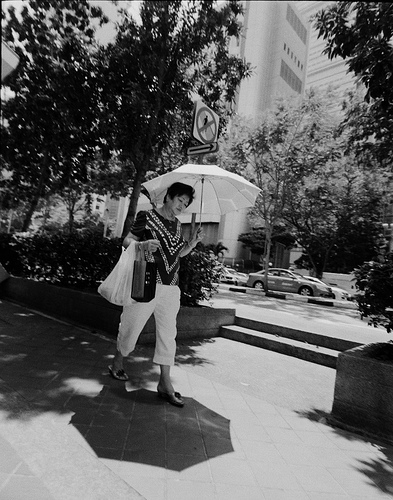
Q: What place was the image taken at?
A: It was taken at the street.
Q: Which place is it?
A: It is a street.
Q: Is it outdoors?
A: Yes, it is outdoors.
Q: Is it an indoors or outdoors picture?
A: It is outdoors.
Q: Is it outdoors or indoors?
A: It is outdoors.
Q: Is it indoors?
A: No, it is outdoors.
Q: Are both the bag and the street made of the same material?
A: No, the bag is made of plastic and the street is made of concrete.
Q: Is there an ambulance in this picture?
A: No, there are no ambulances.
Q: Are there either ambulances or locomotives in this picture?
A: No, there are no ambulances or locomotives.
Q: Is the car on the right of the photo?
A: Yes, the car is on the right of the image.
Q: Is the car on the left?
A: No, the car is on the right of the image.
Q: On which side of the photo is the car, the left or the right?
A: The car is on the right of the image.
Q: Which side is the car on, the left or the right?
A: The car is on the right of the image.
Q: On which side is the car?
A: The car is on the right of the image.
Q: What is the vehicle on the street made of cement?
A: The vehicle is a car.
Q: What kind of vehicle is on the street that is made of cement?
A: The vehicle is a car.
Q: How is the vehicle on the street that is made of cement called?
A: The vehicle is a car.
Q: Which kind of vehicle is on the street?
A: The vehicle is a car.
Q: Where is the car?
A: The car is on the street.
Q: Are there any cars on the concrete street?
A: Yes, there is a car on the street.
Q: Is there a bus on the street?
A: No, there is a car on the street.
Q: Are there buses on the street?
A: No, there is a car on the street.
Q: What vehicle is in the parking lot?
A: The vehicle is a car.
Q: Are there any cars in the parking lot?
A: Yes, there is a car in the parking lot.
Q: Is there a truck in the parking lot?
A: No, there is a car in the parking lot.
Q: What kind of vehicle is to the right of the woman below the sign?
A: The vehicle is a car.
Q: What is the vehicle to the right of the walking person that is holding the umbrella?
A: The vehicle is a car.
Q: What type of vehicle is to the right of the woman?
A: The vehicle is a car.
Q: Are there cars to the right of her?
A: Yes, there is a car to the right of the woman.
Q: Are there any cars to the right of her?
A: Yes, there is a car to the right of the woman.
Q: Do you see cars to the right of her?
A: Yes, there is a car to the right of the woman.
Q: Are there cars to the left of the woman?
A: No, the car is to the right of the woman.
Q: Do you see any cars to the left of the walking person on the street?
A: No, the car is to the right of the woman.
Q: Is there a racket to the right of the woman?
A: No, there is a car to the right of the woman.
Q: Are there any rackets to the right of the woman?
A: No, there is a car to the right of the woman.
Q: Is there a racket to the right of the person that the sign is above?
A: No, there is a car to the right of the woman.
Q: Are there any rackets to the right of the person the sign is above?
A: No, there is a car to the right of the woman.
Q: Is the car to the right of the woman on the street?
A: Yes, the car is to the right of the woman.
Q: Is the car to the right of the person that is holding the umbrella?
A: Yes, the car is to the right of the woman.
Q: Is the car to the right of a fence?
A: No, the car is to the right of the woman.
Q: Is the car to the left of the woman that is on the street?
A: No, the car is to the right of the woman.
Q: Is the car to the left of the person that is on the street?
A: No, the car is to the right of the woman.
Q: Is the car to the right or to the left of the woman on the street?
A: The car is to the right of the woman.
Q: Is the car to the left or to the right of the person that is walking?
A: The car is to the right of the woman.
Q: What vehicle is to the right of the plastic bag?
A: The vehicle is a car.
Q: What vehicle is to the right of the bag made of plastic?
A: The vehicle is a car.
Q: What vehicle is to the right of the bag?
A: The vehicle is a car.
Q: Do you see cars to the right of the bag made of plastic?
A: Yes, there is a car to the right of the bag.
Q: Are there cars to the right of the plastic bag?
A: Yes, there is a car to the right of the bag.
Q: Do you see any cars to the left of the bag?
A: No, the car is to the right of the bag.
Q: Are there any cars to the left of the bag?
A: No, the car is to the right of the bag.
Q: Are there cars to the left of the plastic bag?
A: No, the car is to the right of the bag.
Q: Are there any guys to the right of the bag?
A: No, there is a car to the right of the bag.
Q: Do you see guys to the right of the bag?
A: No, there is a car to the right of the bag.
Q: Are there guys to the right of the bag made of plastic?
A: No, there is a car to the right of the bag.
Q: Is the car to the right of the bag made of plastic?
A: Yes, the car is to the right of the bag.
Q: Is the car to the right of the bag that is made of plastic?
A: Yes, the car is to the right of the bag.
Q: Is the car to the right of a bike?
A: No, the car is to the right of the bag.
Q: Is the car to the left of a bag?
A: No, the car is to the right of a bag.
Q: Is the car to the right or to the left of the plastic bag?
A: The car is to the right of the bag.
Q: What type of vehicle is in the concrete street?
A: The vehicle is a car.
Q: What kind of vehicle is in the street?
A: The vehicle is a car.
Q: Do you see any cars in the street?
A: Yes, there is a car in the street.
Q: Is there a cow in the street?
A: No, there is a car in the street.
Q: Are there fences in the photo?
A: No, there are no fences.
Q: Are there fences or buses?
A: No, there are no fences or buses.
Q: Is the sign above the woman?
A: Yes, the sign is above the woman.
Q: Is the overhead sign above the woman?
A: Yes, the sign is above the woman.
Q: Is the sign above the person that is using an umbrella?
A: Yes, the sign is above the woman.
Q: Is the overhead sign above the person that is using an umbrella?
A: Yes, the sign is above the woman.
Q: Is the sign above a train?
A: No, the sign is above the woman.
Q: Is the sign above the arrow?
A: Yes, the sign is above the arrow.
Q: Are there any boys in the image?
A: No, there are no boys.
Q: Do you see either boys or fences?
A: No, there are no boys or fences.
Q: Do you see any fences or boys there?
A: No, there are no boys or fences.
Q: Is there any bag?
A: Yes, there is a bag.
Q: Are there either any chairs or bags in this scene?
A: Yes, there is a bag.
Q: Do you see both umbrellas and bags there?
A: Yes, there are both a bag and an umbrella.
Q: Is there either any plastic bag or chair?
A: Yes, there is a plastic bag.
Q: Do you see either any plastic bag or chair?
A: Yes, there is a plastic bag.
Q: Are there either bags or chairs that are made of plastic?
A: Yes, the bag is made of plastic.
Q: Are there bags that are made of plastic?
A: Yes, there is a bag that is made of plastic.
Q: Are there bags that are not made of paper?
A: Yes, there is a bag that is made of plastic.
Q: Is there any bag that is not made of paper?
A: Yes, there is a bag that is made of plastic.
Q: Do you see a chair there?
A: No, there are no chairs.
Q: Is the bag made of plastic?
A: Yes, the bag is made of plastic.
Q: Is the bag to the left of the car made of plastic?
A: Yes, the bag is made of plastic.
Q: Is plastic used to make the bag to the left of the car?
A: Yes, the bag is made of plastic.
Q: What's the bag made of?
A: The bag is made of plastic.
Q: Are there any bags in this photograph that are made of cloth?
A: No, there is a bag but it is made of plastic.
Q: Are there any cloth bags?
A: No, there is a bag but it is made of plastic.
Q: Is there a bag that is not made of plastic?
A: No, there is a bag but it is made of plastic.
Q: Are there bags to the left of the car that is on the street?
A: Yes, there is a bag to the left of the car.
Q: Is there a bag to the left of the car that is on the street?
A: Yes, there is a bag to the left of the car.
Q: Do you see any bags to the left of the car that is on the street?
A: Yes, there is a bag to the left of the car.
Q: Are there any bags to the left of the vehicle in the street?
A: Yes, there is a bag to the left of the car.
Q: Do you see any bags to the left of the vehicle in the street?
A: Yes, there is a bag to the left of the car.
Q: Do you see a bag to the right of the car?
A: No, the bag is to the left of the car.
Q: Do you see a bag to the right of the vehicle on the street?
A: No, the bag is to the left of the car.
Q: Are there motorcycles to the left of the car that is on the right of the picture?
A: No, there is a bag to the left of the car.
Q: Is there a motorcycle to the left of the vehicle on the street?
A: No, there is a bag to the left of the car.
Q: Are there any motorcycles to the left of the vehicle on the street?
A: No, there is a bag to the left of the car.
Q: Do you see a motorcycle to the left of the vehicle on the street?
A: No, there is a bag to the left of the car.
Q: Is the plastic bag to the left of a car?
A: Yes, the bag is to the left of a car.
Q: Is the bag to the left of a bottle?
A: No, the bag is to the left of a car.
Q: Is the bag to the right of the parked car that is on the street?
A: No, the bag is to the left of the car.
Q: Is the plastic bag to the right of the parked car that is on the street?
A: No, the bag is to the left of the car.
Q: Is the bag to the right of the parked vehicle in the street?
A: No, the bag is to the left of the car.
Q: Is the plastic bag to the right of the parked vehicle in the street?
A: No, the bag is to the left of the car.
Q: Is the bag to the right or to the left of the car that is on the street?
A: The bag is to the left of the car.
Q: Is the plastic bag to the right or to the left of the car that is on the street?
A: The bag is to the left of the car.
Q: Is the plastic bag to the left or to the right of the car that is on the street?
A: The bag is to the left of the car.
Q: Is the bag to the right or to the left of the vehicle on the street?
A: The bag is to the left of the car.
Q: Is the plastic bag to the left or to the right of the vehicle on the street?
A: The bag is to the left of the car.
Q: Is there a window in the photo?
A: Yes, there are windows.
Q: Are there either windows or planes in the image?
A: Yes, there are windows.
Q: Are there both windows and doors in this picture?
A: No, there are windows but no doors.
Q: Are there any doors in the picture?
A: No, there are no doors.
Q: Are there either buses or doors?
A: No, there are no doors or buses.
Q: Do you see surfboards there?
A: No, there are no surfboards.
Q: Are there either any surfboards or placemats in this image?
A: No, there are no surfboards or placemats.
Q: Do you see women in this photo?
A: Yes, there is a woman.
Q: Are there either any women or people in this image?
A: Yes, there is a woman.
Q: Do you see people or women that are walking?
A: Yes, the woman is walking.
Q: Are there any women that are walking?
A: Yes, there is a woman that is walking.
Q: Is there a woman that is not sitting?
A: Yes, there is a woman that is walking.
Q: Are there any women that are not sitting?
A: Yes, there is a woman that is walking.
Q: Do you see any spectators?
A: No, there are no spectators.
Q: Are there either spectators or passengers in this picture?
A: No, there are no spectators or passengers.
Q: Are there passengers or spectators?
A: No, there are no spectators or passengers.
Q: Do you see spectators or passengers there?
A: No, there are no spectators or passengers.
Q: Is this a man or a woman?
A: This is a woman.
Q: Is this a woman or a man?
A: This is a woman.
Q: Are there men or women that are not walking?
A: No, there is a woman but she is walking.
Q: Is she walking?
A: Yes, the woman is walking.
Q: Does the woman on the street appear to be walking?
A: Yes, the woman is walking.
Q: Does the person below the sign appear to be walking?
A: Yes, the woman is walking.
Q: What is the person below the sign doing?
A: The woman is walking.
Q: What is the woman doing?
A: The woman is walking.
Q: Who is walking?
A: The woman is walking.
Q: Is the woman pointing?
A: No, the woman is walking.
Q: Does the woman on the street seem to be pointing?
A: No, the woman is walking.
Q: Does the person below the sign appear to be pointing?
A: No, the woman is walking.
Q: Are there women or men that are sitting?
A: No, there is a woman but she is walking.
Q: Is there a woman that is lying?
A: No, there is a woman but she is walking.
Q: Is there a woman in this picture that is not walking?
A: No, there is a woman but she is walking.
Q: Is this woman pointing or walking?
A: The woman is walking.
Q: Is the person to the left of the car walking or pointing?
A: The woman is walking.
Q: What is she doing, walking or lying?
A: The woman is walking.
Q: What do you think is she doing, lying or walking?
A: The woman is walking.